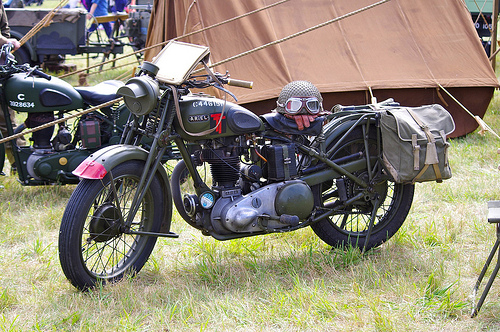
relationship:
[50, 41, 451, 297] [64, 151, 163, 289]
cycle has wheel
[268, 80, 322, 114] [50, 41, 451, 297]
helmet on cycle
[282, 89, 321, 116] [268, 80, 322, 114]
goggles on helmet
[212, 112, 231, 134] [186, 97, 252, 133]
marks on gas tank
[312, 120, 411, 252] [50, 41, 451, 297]
back wheel on cycle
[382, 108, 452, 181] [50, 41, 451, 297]
pack on cycle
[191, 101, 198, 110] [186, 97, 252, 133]
c on gas tank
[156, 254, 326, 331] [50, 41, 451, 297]
grass under cycle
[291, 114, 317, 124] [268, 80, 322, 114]
glove under helmet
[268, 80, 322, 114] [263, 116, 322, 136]
helmet on seat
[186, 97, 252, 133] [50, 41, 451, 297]
gas tank on cycle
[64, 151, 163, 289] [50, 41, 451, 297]
wheel on cycle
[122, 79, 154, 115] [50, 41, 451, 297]
headlight on cycle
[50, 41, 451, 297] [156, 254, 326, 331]
cycle on grass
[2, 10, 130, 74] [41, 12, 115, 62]
truck has bed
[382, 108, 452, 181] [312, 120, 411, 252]
pack anchored to back wheel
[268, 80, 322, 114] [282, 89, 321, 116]
helmet has goggles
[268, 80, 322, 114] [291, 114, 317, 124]
helmet has glove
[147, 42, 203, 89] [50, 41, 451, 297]
windshield on cycle